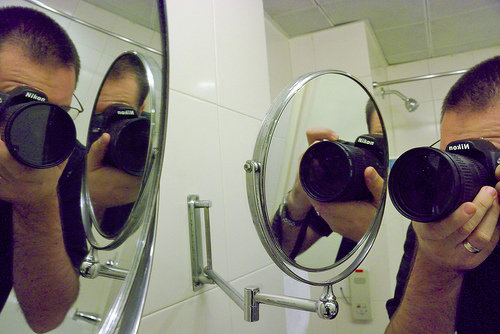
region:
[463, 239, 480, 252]
the ring on the man's finger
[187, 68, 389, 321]
the mirror attached to the wall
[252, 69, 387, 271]
the circle shaped mirror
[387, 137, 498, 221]
the camera the man is holding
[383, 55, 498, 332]
the man holding the camera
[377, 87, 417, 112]
the shower head in the shower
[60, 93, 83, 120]
the glasses on the man's face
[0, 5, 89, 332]
the reflection of the man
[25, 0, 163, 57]
the reflection of the shower rod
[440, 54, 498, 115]
the hair on the man's head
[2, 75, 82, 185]
Man taking a photo in the mirror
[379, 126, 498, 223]
Man taking a photo in the mirror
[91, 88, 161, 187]
Man taking a photo in the mirror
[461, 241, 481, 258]
Man wearing a wedding ring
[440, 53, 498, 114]
man with black hair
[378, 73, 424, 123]
Shower head on the wall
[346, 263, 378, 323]
remote control on the wall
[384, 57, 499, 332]
The photo taking man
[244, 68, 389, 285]
A mirror reflection of a man photographer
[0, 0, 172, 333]
The mirror reflection on the left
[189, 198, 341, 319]
The metallic mirror handle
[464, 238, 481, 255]
A golden worn ring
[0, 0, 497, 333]
The white painted room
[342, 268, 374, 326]
The white room controls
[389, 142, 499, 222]
A dark automatic camera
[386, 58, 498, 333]
A man wearing a dark top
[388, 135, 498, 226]
The dark lens camera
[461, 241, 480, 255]
Wedding ring on man's hand.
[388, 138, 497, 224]
Nikon camera on man's face.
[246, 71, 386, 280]
Silver circle mirror angled.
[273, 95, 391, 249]
Reflection of man in the mirror.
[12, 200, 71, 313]
Man's hairy fore arms.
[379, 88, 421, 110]
Silver shower head in background.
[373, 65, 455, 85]
Silver shower curtain rod.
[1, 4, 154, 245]
Man's double reflection in the mirror.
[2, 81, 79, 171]
a man with a camera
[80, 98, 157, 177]
a man with a camera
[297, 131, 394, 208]
a man with a camera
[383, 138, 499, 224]
a man with a camera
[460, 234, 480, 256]
a man with a gold ring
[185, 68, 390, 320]
a metal mirror on the wall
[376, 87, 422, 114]
a metal shower head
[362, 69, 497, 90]
a metal shower rod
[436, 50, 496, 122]
a man with black hair